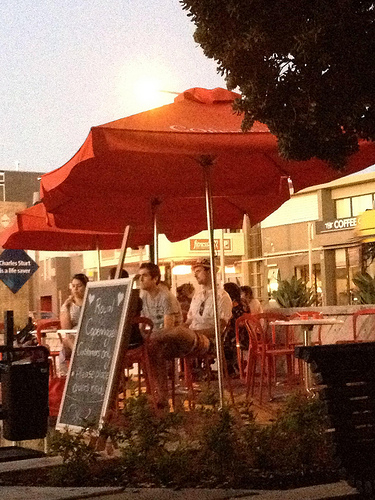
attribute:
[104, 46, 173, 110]
glare — yellow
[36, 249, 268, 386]
patrons — enjoying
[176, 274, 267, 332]
people — group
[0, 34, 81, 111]
sky — overcast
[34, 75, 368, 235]
umbrella — red, big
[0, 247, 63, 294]
sign — promotional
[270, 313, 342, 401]
table — empty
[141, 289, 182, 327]
t-shirt — gray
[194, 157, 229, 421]
stand — silver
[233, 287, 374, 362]
table — empty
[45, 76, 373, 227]
umbrella — large, red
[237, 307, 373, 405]
chairs — red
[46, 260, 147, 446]
chalkboard — small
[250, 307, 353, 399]
chair — red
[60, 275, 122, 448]
menu — written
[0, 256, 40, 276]
writing — white